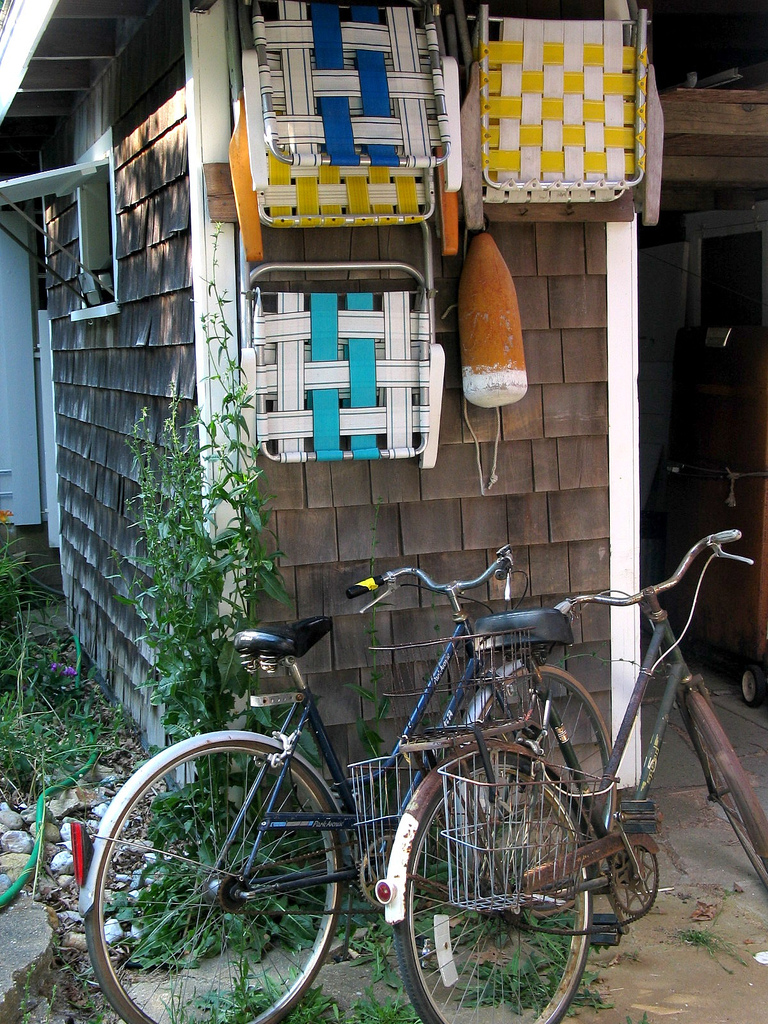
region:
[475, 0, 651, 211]
yellow and white beach chair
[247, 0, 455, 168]
dark blue and white beach chair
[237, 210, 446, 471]
light blue and white beach chair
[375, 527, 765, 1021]
an old rusty bicycle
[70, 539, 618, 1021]
bicycle with yellow and black handle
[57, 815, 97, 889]
red and black back light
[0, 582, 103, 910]
yellow and green water hose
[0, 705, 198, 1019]
bunch of rocks and stones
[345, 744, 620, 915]
two wire bicycle racks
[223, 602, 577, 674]
two black bicycle seats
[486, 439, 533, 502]
wood shingle on side of wall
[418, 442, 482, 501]
wood shingle on side of wall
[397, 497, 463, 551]
wood shingle on side of wall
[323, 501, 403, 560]
wood shingle on side of wall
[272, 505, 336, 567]
wood shingle on side of wall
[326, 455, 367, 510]
wood shingle on side of wall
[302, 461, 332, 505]
wood shingle on side of wall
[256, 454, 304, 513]
wood shingle on side of wall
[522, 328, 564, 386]
wood shingle on side of wall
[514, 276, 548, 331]
wood shingle on side of wall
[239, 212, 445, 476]
a white and teal lawn chair hanging on a house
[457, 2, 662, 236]
a white and yellow lawn chair hanging on a house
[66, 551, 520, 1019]
a blue bike leaning on a house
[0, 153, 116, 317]
an open window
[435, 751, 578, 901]
a basket on a bike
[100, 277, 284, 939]
tall weeds growing beside a house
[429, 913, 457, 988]
a white reflector in bike spokes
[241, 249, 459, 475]
blue and white folding chair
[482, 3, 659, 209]
yellow and white folding chair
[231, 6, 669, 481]
folding chairs hanging on the wall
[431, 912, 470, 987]
reflector on the spokes of the bike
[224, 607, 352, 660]
black leather bike seat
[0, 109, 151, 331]
the window is open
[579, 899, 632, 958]
black pedal on the bike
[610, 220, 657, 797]
white paint on the corner of the house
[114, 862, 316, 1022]
wheel of the bike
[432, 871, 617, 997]
wheel of the bike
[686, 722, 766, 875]
wheel of the bike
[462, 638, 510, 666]
seat of hte bike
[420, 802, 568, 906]
basket on the bike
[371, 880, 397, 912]
light on the bike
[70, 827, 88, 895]
light on the bike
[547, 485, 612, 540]
wood siding is brown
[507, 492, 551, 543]
wood siding is brown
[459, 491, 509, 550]
wood siding is brown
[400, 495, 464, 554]
wood siding is brown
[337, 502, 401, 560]
wood siding is brown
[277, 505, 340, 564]
wood siding is brown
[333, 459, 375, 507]
wood siding is brown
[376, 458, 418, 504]
wood siding is brown